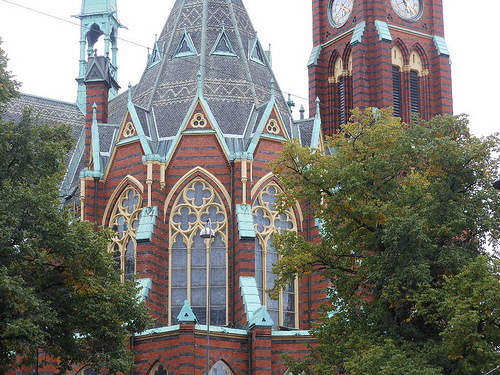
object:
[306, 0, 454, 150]
tower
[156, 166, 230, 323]
window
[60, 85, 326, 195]
roof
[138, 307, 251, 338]
balcony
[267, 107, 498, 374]
tree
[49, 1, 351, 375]
church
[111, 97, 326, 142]
trim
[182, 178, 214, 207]
circles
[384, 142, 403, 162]
leaves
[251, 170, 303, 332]
windows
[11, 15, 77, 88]
sky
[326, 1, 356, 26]
clocks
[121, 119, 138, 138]
windows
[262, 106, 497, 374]
trees